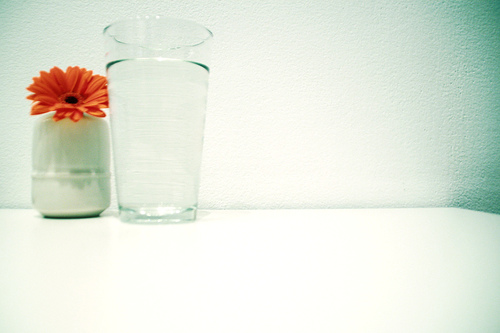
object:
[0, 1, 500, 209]
wall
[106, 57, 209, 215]
water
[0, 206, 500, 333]
table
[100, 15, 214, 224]
glass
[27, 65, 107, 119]
flower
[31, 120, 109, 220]
vase